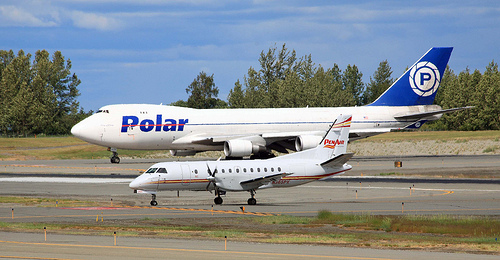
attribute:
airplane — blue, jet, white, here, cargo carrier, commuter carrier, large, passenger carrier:
[69, 45, 479, 165]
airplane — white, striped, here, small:
[126, 112, 356, 207]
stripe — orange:
[149, 174, 334, 185]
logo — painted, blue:
[120, 113, 190, 133]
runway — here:
[1, 153, 499, 176]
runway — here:
[0, 176, 499, 223]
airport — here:
[1, 129, 499, 259]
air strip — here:
[1, 229, 499, 259]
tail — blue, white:
[361, 46, 455, 106]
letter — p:
[419, 71, 432, 86]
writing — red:
[323, 138, 346, 146]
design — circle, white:
[409, 60, 442, 96]